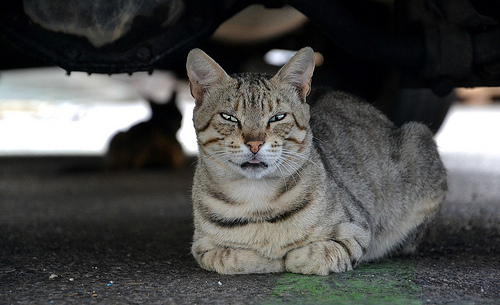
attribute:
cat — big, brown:
[181, 45, 451, 275]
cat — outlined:
[73, 93, 183, 172]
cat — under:
[107, 88, 185, 168]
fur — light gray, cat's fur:
[208, 196, 295, 224]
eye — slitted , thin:
[219, 109, 239, 124]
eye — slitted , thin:
[269, 112, 286, 126]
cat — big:
[188, 49, 474, 283]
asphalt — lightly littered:
[18, 244, 157, 301]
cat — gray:
[172, 45, 489, 295]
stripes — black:
[203, 178, 335, 240]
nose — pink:
[242, 133, 266, 155]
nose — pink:
[174, 41, 448, 276]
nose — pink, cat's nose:
[244, 141, 265, 151]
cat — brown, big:
[167, 65, 454, 291]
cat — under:
[172, 49, 456, 266]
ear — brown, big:
[275, 47, 315, 95]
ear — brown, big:
[184, 46, 230, 98]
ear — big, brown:
[167, 86, 180, 103]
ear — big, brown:
[140, 91, 159, 110]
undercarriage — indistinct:
[3, 4, 424, 52]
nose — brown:
[244, 133, 265, 152]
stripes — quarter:
[192, 193, 292, 237]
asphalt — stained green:
[290, 263, 410, 296]